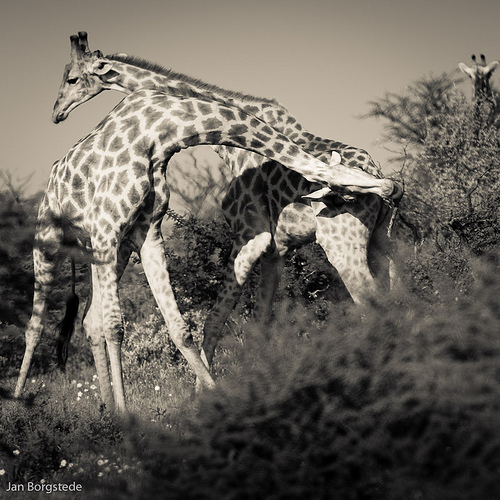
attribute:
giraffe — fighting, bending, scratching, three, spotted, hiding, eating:
[49, 36, 262, 176]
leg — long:
[306, 230, 406, 325]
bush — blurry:
[273, 350, 464, 480]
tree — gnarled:
[427, 145, 490, 243]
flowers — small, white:
[84, 374, 106, 397]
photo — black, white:
[8, 6, 464, 498]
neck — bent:
[130, 60, 248, 115]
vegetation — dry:
[14, 192, 63, 295]